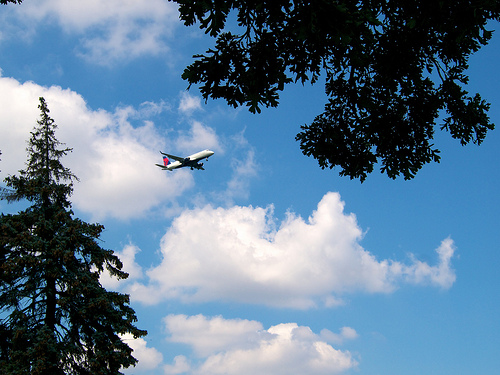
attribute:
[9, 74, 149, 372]
tree — tall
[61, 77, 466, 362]
sky — partly cloudy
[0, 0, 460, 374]
clouds — like smoke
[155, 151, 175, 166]
tail — red, blue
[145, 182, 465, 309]
cloud — white, puffy 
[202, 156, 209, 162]
front wheel — down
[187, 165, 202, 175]
wheels — down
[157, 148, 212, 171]
plane — white, blue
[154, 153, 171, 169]
tail — red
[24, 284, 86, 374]
branches — thick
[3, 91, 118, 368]
tree — evergreen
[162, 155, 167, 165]
paint — red, blue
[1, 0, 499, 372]
sky — blue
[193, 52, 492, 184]
leaves — dark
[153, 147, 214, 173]
plane — white